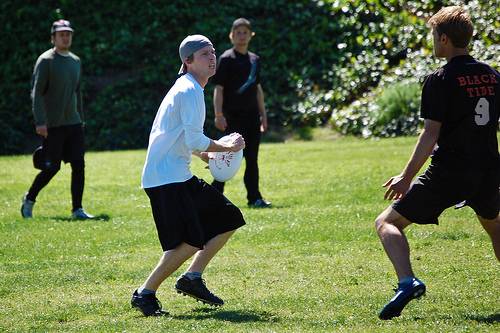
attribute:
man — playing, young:
[127, 33, 248, 318]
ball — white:
[210, 137, 244, 183]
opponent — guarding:
[373, 7, 499, 321]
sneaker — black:
[173, 274, 226, 308]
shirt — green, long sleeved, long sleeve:
[32, 48, 88, 126]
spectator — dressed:
[212, 17, 269, 206]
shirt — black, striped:
[212, 49, 262, 121]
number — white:
[474, 97, 489, 128]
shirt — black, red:
[419, 56, 499, 169]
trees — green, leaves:
[0, 2, 499, 153]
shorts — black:
[143, 175, 246, 251]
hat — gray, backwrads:
[177, 33, 215, 77]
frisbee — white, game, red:
[207, 137, 242, 183]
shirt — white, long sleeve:
[140, 75, 212, 189]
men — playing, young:
[20, 6, 498, 322]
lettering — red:
[457, 72, 498, 97]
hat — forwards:
[50, 20, 73, 35]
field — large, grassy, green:
[0, 128, 496, 333]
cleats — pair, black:
[130, 274, 223, 315]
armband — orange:
[215, 112, 224, 117]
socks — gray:
[138, 272, 203, 294]